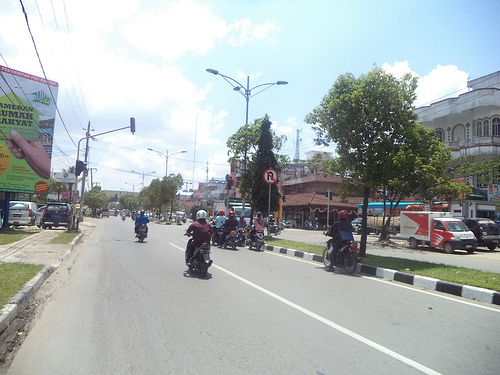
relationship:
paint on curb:
[361, 264, 376, 276] [263, 241, 499, 306]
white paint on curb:
[463, 290, 489, 299] [266, 243, 498, 312]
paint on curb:
[353, 263, 437, 287] [263, 241, 499, 306]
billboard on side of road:
[0, 65, 59, 195] [0, 215, 500, 375]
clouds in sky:
[1, 0, 474, 193] [4, 1, 494, 199]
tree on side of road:
[323, 61, 475, 264] [18, 214, 484, 373]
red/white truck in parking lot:
[396, 212, 479, 253] [378, 232, 498, 253]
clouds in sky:
[83, 16, 251, 136] [4, 1, 494, 199]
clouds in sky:
[9, 5, 276, 147] [88, 57, 205, 107]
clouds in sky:
[0, 0, 290, 130] [233, 2, 457, 92]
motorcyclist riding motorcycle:
[135, 210, 150, 239] [128, 220, 149, 242]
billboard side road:
[1, 65, 62, 197] [70, 204, 137, 274]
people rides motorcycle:
[207, 206, 269, 248] [211, 223, 239, 251]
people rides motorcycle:
[207, 206, 269, 248] [235, 226, 250, 247]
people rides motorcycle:
[207, 206, 269, 248] [246, 228, 267, 253]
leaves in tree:
[337, 74, 409, 196] [320, 76, 414, 258]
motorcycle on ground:
[181, 223, 215, 275] [390, 145, 417, 168]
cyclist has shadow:
[182, 210, 217, 263] [182, 270, 214, 282]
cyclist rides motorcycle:
[184, 209, 214, 266] [183, 235, 220, 280]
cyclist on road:
[184, 209, 214, 266] [128, 295, 251, 355]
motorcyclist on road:
[325, 207, 350, 241] [128, 295, 251, 355]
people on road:
[246, 212, 267, 247] [128, 295, 251, 355]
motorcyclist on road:
[132, 211, 150, 226] [128, 295, 251, 355]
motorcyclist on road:
[215, 208, 225, 232] [128, 295, 251, 355]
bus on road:
[354, 200, 447, 237] [275, 223, 499, 269]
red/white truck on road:
[399, 210, 479, 253] [275, 223, 499, 269]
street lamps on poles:
[202, 50, 316, 127] [226, 89, 271, 164]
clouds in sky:
[86, 11, 203, 109] [109, 10, 494, 121]